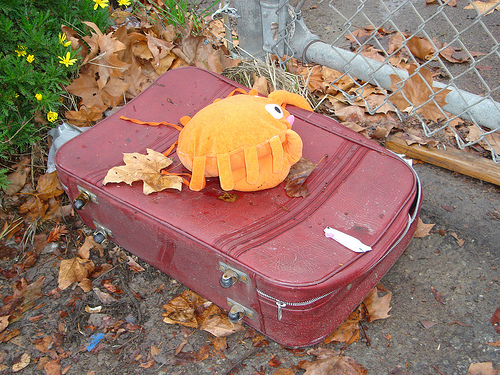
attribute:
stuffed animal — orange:
[155, 83, 314, 190]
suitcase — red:
[51, 56, 434, 311]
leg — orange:
[190, 152, 209, 194]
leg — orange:
[214, 154, 243, 190]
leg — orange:
[244, 151, 265, 190]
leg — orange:
[269, 134, 289, 171]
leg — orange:
[270, 85, 307, 110]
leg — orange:
[178, 111, 192, 128]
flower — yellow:
[89, 0, 111, 13]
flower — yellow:
[116, 1, 134, 9]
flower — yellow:
[26, 53, 45, 64]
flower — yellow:
[59, 35, 71, 47]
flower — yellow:
[32, 90, 51, 103]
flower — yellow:
[43, 108, 68, 126]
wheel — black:
[69, 196, 101, 208]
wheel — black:
[93, 230, 108, 250]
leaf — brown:
[50, 245, 95, 287]